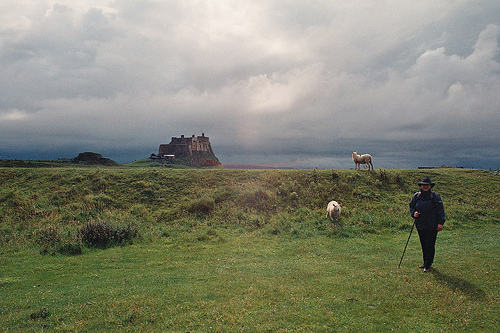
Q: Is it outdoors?
A: Yes, it is outdoors.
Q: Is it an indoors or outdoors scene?
A: It is outdoors.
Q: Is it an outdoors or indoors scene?
A: It is outdoors.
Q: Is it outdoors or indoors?
A: It is outdoors.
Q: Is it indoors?
A: No, it is outdoors.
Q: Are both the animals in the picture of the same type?
A: Yes, all the animals are sheep.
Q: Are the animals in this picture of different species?
A: No, all the animals are sheep.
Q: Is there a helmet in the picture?
A: No, there are no helmets.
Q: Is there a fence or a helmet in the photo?
A: No, there are no helmets or fences.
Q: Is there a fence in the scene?
A: No, there are no fences.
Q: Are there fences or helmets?
A: No, there are no fences or helmets.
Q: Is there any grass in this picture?
A: Yes, there is grass.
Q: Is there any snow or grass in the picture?
A: Yes, there is grass.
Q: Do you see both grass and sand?
A: No, there is grass but no sand.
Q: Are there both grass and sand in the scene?
A: No, there is grass but no sand.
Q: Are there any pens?
A: No, there are no pens.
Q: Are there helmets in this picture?
A: No, there are no helmets.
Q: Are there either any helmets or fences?
A: No, there are no helmets or fences.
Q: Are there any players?
A: No, there are no players.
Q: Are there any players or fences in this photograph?
A: No, there are no players or fences.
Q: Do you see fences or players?
A: No, there are no players or fences.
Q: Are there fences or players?
A: No, there are no players or fences.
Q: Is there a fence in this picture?
A: No, there are no fences.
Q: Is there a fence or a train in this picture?
A: No, there are no fences or trains.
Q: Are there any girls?
A: No, there are no girls.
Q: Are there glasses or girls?
A: No, there are no girls or glasses.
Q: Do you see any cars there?
A: No, there are no cars.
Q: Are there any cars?
A: No, there are no cars.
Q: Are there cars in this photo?
A: No, there are no cars.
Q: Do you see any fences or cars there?
A: No, there are no cars or fences.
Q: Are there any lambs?
A: Yes, there is a lamb.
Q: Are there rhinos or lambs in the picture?
A: Yes, there is a lamb.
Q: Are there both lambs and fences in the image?
A: No, there is a lamb but no fences.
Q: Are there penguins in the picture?
A: No, there are no penguins.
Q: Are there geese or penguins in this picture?
A: No, there are no penguins or geese.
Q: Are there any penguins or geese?
A: No, there are no penguins or geese.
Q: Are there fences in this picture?
A: No, there are no fences.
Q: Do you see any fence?
A: No, there are no fences.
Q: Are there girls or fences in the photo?
A: No, there are no fences or girls.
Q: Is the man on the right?
A: Yes, the man is on the right of the image.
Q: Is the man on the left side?
A: No, the man is on the right of the image.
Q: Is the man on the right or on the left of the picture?
A: The man is on the right of the image.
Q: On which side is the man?
A: The man is on the right of the image.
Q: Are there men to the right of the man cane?
A: Yes, there is a man to the right of the cane.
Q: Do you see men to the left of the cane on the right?
A: No, the man is to the right of the cane.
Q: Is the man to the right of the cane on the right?
A: Yes, the man is to the right of the cane.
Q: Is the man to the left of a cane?
A: No, the man is to the right of a cane.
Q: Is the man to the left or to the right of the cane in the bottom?
A: The man is to the right of the cane.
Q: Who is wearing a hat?
A: The man is wearing a hat.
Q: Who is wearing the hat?
A: The man is wearing a hat.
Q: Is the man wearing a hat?
A: Yes, the man is wearing a hat.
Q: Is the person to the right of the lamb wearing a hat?
A: Yes, the man is wearing a hat.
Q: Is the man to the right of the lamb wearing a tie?
A: No, the man is wearing a hat.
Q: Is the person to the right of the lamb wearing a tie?
A: No, the man is wearing a hat.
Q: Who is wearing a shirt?
A: The man is wearing a shirt.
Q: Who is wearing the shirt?
A: The man is wearing a shirt.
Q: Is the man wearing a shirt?
A: Yes, the man is wearing a shirt.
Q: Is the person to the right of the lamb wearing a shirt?
A: Yes, the man is wearing a shirt.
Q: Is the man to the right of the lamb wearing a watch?
A: No, the man is wearing a shirt.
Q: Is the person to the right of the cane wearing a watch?
A: No, the man is wearing a shirt.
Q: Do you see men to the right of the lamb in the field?
A: Yes, there is a man to the right of the lamb.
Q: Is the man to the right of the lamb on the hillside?
A: Yes, the man is to the right of the lamb.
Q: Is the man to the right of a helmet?
A: No, the man is to the right of the lamb.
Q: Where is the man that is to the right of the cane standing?
A: The man is standing in the field.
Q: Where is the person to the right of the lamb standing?
A: The man is standing in the field.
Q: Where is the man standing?
A: The man is standing in the field.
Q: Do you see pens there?
A: No, there are no pens.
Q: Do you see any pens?
A: No, there are no pens.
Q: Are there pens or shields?
A: No, there are no pens or shields.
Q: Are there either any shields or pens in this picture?
A: No, there are no pens or shields.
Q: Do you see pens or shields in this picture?
A: No, there are no pens or shields.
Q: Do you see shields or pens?
A: No, there are no pens or shields.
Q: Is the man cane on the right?
A: Yes, the cane is on the right of the image.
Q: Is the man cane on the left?
A: No, the cane is on the right of the image.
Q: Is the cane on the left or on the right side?
A: The cane is on the right of the image.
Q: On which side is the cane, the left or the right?
A: The cane is on the right of the image.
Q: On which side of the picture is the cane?
A: The cane is on the right of the image.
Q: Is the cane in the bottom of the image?
A: Yes, the cane is in the bottom of the image.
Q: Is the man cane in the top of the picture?
A: No, the cane is in the bottom of the image.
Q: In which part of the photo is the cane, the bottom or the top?
A: The cane is in the bottom of the image.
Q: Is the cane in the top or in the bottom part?
A: The cane is in the bottom of the image.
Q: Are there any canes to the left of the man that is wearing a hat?
A: Yes, there is a cane to the left of the man.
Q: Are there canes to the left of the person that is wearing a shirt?
A: Yes, there is a cane to the left of the man.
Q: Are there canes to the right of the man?
A: No, the cane is to the left of the man.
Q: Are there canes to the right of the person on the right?
A: No, the cane is to the left of the man.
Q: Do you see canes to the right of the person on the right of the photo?
A: No, the cane is to the left of the man.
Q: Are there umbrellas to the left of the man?
A: No, there is a cane to the left of the man.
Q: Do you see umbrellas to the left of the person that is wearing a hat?
A: No, there is a cane to the left of the man.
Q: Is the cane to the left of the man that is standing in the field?
A: Yes, the cane is to the left of the man.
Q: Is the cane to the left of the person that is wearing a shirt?
A: Yes, the cane is to the left of the man.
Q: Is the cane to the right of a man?
A: No, the cane is to the left of a man.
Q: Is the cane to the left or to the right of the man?
A: The cane is to the left of the man.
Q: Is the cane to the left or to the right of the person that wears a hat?
A: The cane is to the left of the man.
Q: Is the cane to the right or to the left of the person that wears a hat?
A: The cane is to the left of the man.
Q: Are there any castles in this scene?
A: Yes, there is a castle.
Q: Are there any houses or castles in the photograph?
A: Yes, there is a castle.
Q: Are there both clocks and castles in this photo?
A: No, there is a castle but no clocks.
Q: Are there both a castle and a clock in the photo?
A: No, there is a castle but no clocks.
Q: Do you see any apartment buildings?
A: No, there are no apartment buildings.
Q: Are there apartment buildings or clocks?
A: No, there are no apartment buildings or clocks.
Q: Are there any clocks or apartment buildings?
A: No, there are no apartment buildings or clocks.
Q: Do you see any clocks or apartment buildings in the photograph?
A: No, there are no apartment buildings or clocks.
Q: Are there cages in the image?
A: No, there are no cages.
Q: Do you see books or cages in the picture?
A: No, there are no cages or books.